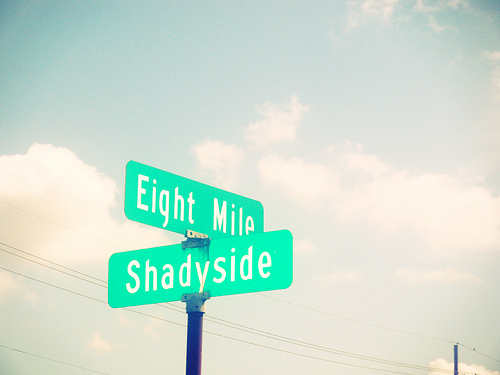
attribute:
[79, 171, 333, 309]
sign — green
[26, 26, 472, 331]
sky — blue, white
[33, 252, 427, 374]
wires — black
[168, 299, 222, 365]
pole — grey, gray, black